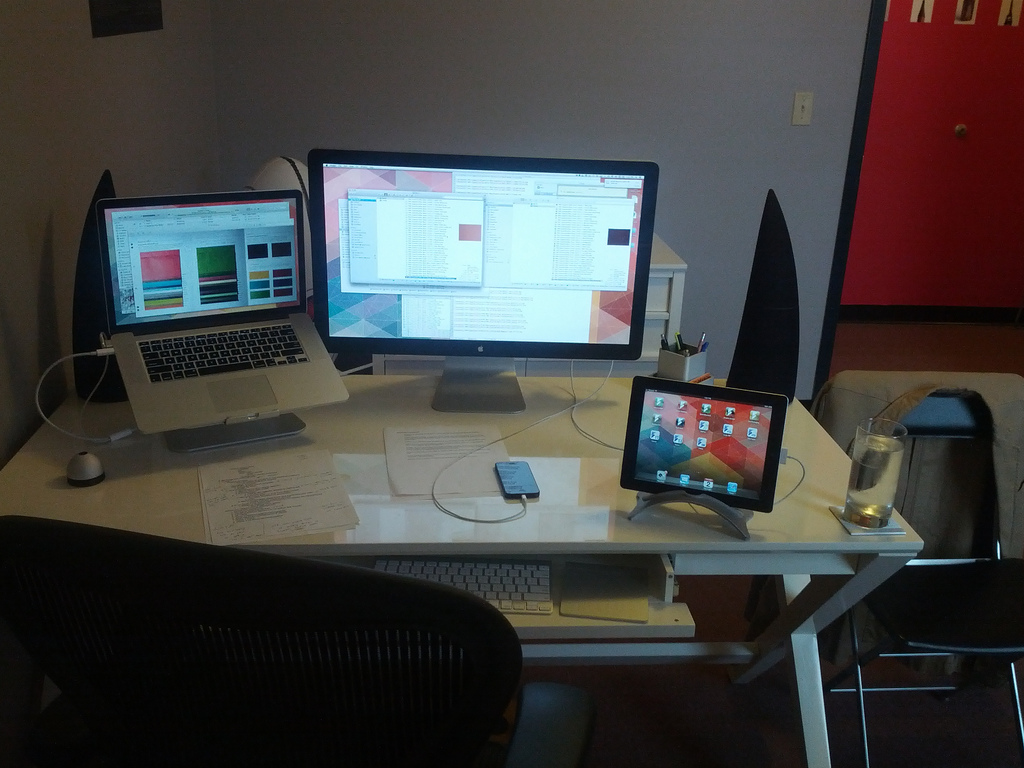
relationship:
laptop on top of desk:
[104, 198, 336, 419] [103, 495, 177, 531]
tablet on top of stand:
[621, 361, 772, 502] [638, 491, 742, 532]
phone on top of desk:
[499, 459, 538, 497] [103, 495, 177, 531]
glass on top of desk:
[848, 419, 893, 532] [103, 495, 177, 531]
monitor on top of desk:
[305, 136, 649, 373] [103, 495, 177, 531]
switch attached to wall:
[782, 84, 819, 125] [419, 40, 643, 98]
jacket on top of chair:
[908, 371, 994, 401] [883, 452, 1015, 707]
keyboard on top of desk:
[371, 550, 553, 616] [103, 495, 177, 531]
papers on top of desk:
[201, 453, 352, 535] [103, 495, 177, 531]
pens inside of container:
[702, 336, 707, 345] [662, 354, 711, 380]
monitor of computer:
[305, 136, 649, 373] [422, 362, 534, 407]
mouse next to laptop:
[64, 440, 100, 498] [104, 198, 336, 419]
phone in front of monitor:
[499, 459, 538, 497] [305, 136, 649, 373]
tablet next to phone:
[621, 361, 772, 502] [499, 459, 538, 497]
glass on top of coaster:
[848, 419, 893, 532] [840, 525, 869, 537]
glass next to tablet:
[848, 419, 893, 532] [621, 361, 772, 502]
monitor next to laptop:
[305, 136, 649, 373] [104, 198, 336, 419]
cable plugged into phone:
[463, 515, 517, 528] [499, 459, 538, 497]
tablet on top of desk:
[621, 361, 772, 502] [103, 495, 177, 531]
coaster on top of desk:
[840, 525, 869, 537] [103, 495, 177, 531]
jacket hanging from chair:
[908, 371, 994, 401] [883, 452, 1015, 707]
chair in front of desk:
[883, 452, 1015, 707] [103, 495, 177, 531]